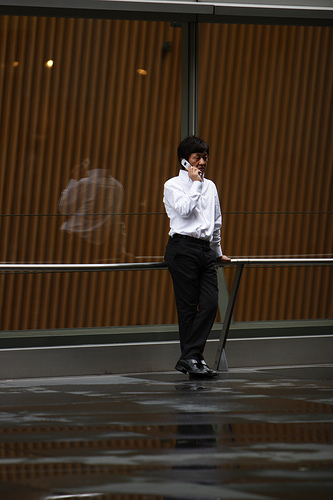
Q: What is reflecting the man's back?
A: Window.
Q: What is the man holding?
A: Cell phone.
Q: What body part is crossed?
A: Ankles.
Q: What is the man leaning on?
A: Rail.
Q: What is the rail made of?
A: Metal.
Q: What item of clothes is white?
A: Shirt.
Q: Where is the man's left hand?
A: On the rail.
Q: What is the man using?
A: Cell phoen.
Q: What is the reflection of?
A: Male.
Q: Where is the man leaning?
A: Handrail.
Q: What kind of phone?
A: Cell phoen.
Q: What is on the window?
A: Reflection.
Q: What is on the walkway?
A: Puddles.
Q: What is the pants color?
A: Black.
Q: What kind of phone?
A: Cell phone.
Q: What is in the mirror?
A: The man's reflection.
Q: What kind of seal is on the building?
A: A window seal.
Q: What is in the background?
A: A brown wall.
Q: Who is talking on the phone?
A: The man.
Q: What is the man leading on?
A: A railing.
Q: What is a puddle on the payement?
A: Water.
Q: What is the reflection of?
A: The man.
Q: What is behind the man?
A: Windows.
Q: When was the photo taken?
A: Day time.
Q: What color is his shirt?
A: White.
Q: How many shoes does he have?
A: Twom.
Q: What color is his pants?
A: Black.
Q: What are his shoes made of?
A: Leather.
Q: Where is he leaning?
A: Against the rail.